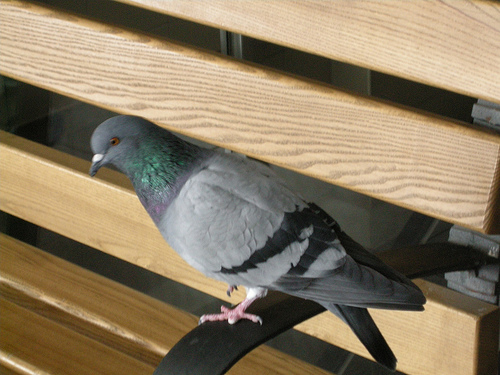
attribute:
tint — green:
[122, 138, 212, 210]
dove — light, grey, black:
[88, 113, 429, 369]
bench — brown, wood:
[3, 4, 499, 374]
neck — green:
[136, 133, 207, 205]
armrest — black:
[146, 239, 499, 374]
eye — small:
[109, 133, 121, 148]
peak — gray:
[90, 152, 104, 177]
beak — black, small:
[92, 157, 102, 176]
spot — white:
[93, 152, 104, 164]